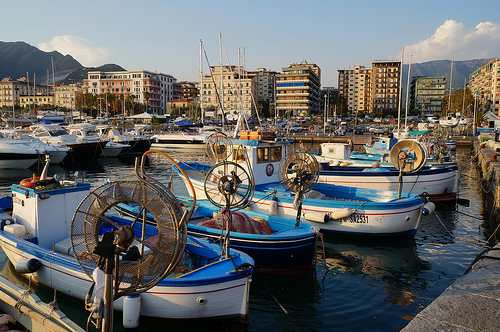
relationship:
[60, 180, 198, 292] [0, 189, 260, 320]
fan on boat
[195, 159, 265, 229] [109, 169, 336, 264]
fan on boat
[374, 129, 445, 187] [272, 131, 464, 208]
fan on boat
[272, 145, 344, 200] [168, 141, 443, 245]
fan on boat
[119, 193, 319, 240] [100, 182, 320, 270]
bed on blue boat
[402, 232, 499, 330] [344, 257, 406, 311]
sidewalk near water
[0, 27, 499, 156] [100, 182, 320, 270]
masts on blue boat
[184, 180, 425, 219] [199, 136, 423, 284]
stripe on boat